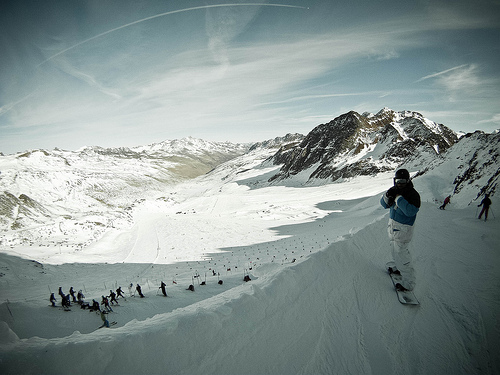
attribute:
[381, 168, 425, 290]
man — snowboarder, alone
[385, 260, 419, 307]
snowboard — white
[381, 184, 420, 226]
jacket — blue, ski jacket, light blue, white, dark blue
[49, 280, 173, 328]
group — skiers, snowboarders, at ground level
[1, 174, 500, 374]
snow — bright, white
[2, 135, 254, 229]
mountain — snowy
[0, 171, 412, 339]
ski slope — ready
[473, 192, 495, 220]
skier — skiing, wearing black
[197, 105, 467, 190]
mountain — snowy, less snowy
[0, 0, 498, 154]
sky — clear, cloudy, blue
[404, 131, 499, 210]
mountain — snowy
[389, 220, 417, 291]
pants — white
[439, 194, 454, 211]
skier — wearing black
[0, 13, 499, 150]
clouds — white